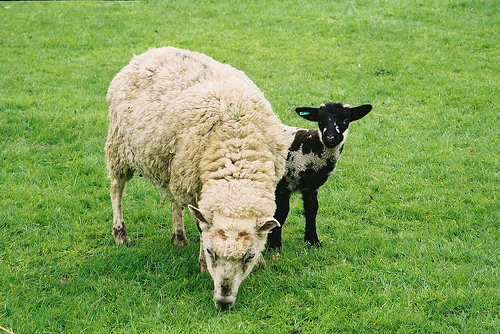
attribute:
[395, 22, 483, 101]
grass — green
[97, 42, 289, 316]
sheep — white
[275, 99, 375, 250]
sheep — black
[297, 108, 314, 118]
tag — blue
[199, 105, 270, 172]
fur — white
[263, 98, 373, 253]
sheep — black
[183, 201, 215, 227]
ear — perky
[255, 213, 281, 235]
ear — perky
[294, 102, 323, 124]
ear — black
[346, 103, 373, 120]
ear — black